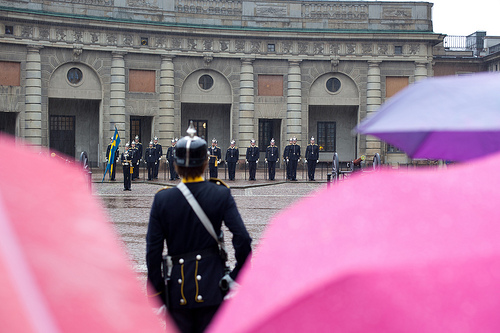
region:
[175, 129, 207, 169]
the soldier is wearing a hat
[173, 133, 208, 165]
the hat is black in color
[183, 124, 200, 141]
the hat has a metal top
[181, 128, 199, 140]
the top of hat is shiny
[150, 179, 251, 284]
the soldier is wearing a jacket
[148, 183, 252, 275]
the jacket is black in color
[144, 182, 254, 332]
the soldier is wearing a uniform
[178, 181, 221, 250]
the soldier has a strap across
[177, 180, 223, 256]
the strap is white in color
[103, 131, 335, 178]
the soldiers are lined up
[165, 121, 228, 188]
head of the person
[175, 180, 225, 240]
strap around the person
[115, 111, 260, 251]
person with back towards camera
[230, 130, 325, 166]
people in a line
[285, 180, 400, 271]
pink object in the photo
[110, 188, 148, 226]
ground next to the people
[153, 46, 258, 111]
building behind the people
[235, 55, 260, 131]
pillar on the building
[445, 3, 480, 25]
sky behind the building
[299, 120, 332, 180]
man standing in line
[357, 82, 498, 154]
UMBRELLA IS PURPLE IN COLOR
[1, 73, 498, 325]
UMBRELLAS ARE UP DUE TO RAIN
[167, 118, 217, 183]
MAN IS WEARING A HELMET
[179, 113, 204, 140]
HELMET HAS A SPIKE ON TOP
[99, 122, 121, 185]
FLAG IS YELLOW AND BLUE IN COLOR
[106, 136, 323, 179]
A GROUP OF MEN STAND AT ATTENTION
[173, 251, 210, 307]
MAN HAS SIX BUTTONS ON HIS BACK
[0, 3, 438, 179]
BUILDING IS IN THE BACK GROUND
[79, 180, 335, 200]
WHITE LINES ARE ON THE GROUND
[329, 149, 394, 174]
A CANNON IS TO THE RIGHT OF THE MEN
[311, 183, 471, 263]
top of pink umbrella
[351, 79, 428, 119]
spine in purple umbrella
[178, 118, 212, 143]
dome on top of black hat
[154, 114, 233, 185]
shiny black hat on head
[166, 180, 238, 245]
white sash around black jacket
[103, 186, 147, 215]
water on the ground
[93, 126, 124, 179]
large blue and yellow flag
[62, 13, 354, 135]
front of tall building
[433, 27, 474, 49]
railing at top of building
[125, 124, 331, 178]
soldiers standing in a row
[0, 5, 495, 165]
the stone wash building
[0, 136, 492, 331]
two pink baracades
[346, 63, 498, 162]
a purple umbrella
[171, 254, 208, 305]
six buttons on suit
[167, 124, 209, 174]
a helmet on man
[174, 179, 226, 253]
a white strap across shoulder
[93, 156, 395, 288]
the grounds are wet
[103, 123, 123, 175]
a blue and yellow flag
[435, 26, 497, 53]
a fence on top of building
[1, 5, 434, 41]
a aqua blue trimming on building